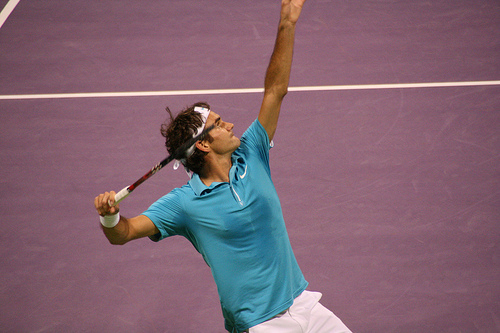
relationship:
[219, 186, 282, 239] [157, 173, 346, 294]
sweat on shirt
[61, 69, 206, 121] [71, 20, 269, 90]
line on court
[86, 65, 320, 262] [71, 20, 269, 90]
man on court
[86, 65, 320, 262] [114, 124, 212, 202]
man with racket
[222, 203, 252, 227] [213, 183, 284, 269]
stains on cloth